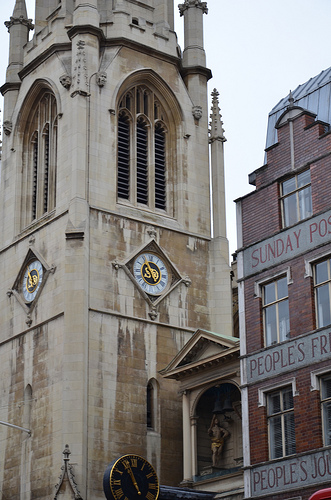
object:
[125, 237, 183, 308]
clock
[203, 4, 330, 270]
sky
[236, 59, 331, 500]
building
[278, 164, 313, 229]
window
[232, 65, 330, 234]
top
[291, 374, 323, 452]
wall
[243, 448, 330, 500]
sign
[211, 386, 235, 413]
bell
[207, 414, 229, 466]
statue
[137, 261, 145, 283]
numbers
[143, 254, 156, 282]
gold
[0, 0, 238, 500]
building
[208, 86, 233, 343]
spire